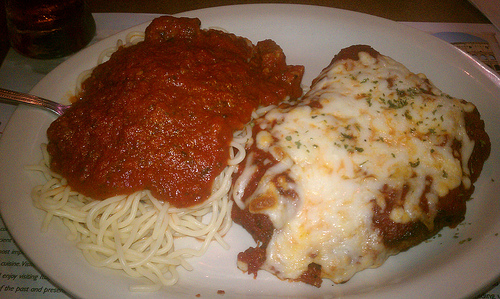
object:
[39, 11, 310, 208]
sauce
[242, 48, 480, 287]
cheese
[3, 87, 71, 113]
fork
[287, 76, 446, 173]
herb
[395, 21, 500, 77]
tablecloth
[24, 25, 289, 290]
noodles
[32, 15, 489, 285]
food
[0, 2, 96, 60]
cup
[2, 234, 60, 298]
newsprint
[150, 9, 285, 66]
meat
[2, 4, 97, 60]
dark beverage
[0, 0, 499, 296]
table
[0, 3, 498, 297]
plate